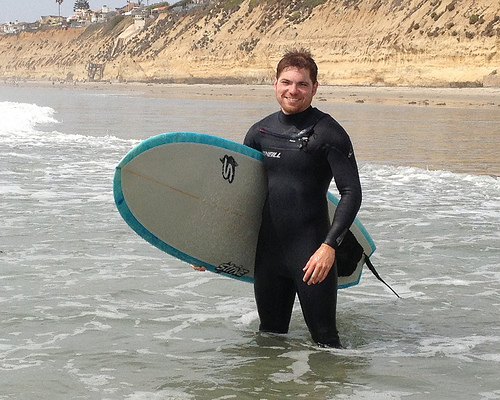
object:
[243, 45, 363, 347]
man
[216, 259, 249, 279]
stine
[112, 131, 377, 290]
board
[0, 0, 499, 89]
mountains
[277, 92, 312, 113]
beard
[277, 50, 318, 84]
hair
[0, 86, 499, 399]
water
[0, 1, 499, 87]
hillside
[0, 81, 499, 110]
beach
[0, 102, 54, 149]
foam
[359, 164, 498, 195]
foam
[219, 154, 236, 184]
sticker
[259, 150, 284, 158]
logo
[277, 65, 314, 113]
man's face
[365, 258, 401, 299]
strap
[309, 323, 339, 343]
knee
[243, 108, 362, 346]
suit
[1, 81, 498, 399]
ocean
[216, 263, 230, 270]
letters